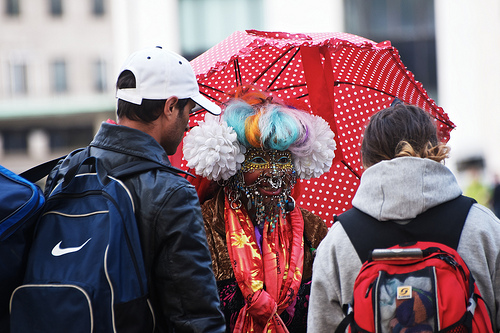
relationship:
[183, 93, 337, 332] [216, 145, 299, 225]
woman has facial piercings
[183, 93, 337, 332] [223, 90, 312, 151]
woman wearing a wig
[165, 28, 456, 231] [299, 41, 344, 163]
umbrella has red ribbon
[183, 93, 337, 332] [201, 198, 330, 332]
woman wearing a jacket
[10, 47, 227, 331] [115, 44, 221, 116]
man wearing cap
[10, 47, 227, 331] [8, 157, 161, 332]
man carrying a backpack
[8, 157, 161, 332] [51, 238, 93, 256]
bag has nike sign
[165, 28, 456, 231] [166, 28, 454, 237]
umbrella has polka dots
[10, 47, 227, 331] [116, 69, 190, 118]
man has brown hair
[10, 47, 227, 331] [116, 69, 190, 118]
man has black hair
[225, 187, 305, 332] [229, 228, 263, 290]
scarf has yellow leaf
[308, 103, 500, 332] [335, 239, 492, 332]
woman has a bag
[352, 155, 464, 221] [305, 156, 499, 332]
hood attached to hoodie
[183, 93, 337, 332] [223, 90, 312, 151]
person has muti-colored hair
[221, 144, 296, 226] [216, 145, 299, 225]
face has piercings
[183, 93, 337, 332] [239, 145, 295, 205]
person wearing a mask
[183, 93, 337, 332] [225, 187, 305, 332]
person wearing a scarf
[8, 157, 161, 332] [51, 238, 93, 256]
backpack has nike symbol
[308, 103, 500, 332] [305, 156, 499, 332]
person wearing hoodie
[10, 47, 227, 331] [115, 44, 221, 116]
man has white cap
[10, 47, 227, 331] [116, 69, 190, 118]
man with short hair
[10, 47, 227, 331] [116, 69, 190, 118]
man with dark hair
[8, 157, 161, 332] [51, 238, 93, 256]
backpack has nike sign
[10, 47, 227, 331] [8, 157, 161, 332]
man carrying backpack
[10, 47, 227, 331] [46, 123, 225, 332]
man wearing jacket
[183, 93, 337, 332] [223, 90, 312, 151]
person has wig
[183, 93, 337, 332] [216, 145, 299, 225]
person has facial piercings